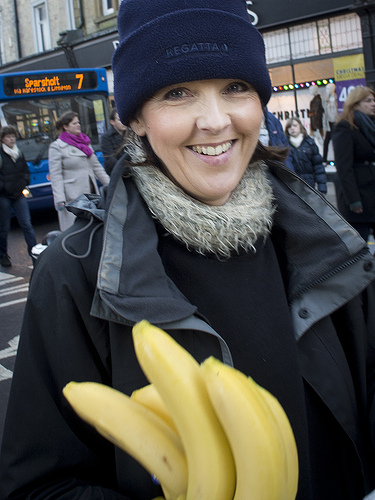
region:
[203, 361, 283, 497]
yellow banana in hand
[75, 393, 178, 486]
yellow banana in hand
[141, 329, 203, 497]
yellow banana in hand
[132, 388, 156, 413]
yellow banana in hand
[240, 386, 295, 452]
yellow banana in hand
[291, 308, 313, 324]
button on the jacket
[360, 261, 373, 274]
button on the jacket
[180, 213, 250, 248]
scarf on the woman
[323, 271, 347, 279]
zipper on the jacket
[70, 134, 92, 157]
scarf on the woman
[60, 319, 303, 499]
a bunch of bananas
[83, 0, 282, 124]
part of a blue cap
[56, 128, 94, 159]
a woman's purple scarf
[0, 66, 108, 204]
part of a blue bus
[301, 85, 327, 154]
a white mannequin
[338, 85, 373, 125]
a woman's long brown hair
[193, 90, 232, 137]
the nose of a woman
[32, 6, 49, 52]
a window of a building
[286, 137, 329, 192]
a woman's black coat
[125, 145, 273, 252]
a woman's furry collar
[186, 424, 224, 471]
bananas in woman's hand.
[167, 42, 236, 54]
writing on woman's hat.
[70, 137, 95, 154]
scarf on woman's neck.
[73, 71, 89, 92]
number on the bus.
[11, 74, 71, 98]
writing on the bus.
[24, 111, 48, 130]
windshield on the bus.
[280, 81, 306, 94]
lights on the building.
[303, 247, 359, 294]
zipper on woman's coat.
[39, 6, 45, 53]
window on the building.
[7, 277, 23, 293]
white paint on the street.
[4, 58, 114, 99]
lighted route on a bus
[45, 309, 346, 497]
bunch of yellow bananas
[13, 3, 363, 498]
woman in the street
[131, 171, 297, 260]
scarf of a woman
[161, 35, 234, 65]
logo on a hat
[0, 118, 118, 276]
people walking in the street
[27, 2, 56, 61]
window of a building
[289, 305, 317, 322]
button on a jacket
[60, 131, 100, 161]
purple scarf on a woman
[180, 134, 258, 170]
smile on a woman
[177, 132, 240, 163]
she is smiling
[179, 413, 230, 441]
the bananas are yellow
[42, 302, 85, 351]
the coat is black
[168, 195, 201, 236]
the scarf is white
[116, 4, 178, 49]
the hat is blue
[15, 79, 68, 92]
the words are orange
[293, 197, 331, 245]
the inside is gray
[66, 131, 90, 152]
the scarf is purple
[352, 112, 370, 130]
the scarf is gray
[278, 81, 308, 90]
the lights are multi color